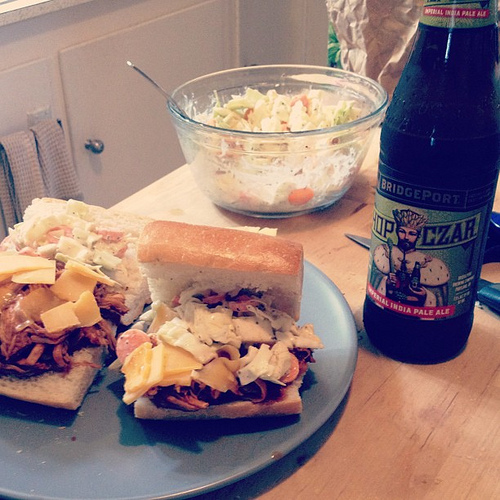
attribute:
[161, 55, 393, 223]
bowl — clear, homemade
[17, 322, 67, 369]
meat — pulled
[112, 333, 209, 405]
cheese — white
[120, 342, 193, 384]
slices — orange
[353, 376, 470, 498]
table — wooden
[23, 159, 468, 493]
plate — round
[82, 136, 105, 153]
knob — silver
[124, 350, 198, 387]
cheddar cheese — sliced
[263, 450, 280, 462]
brown spot — tiny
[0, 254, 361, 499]
plate — pale blue, blue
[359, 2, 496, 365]
bottle — dark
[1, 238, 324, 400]
pulled pork — homemade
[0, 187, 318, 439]
sandwiches — open-faced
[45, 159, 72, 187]
towels — plaid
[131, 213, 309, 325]
sandwich bread — white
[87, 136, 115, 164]
door knob — small, silver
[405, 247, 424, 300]
beer — pale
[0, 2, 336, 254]
cabinet — white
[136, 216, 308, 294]
crust — tan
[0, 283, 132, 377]
meat — brown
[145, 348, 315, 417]
meat — brown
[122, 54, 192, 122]
spoon — large